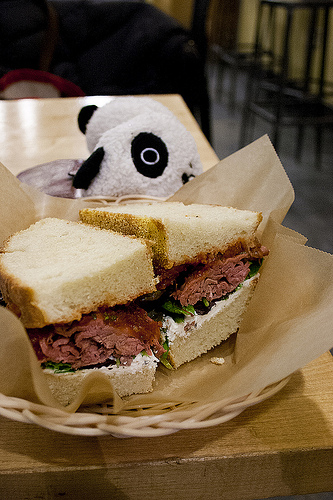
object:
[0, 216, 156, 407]
sandwhich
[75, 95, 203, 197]
stuffed animal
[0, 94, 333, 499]
table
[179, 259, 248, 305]
meat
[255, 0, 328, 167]
stool